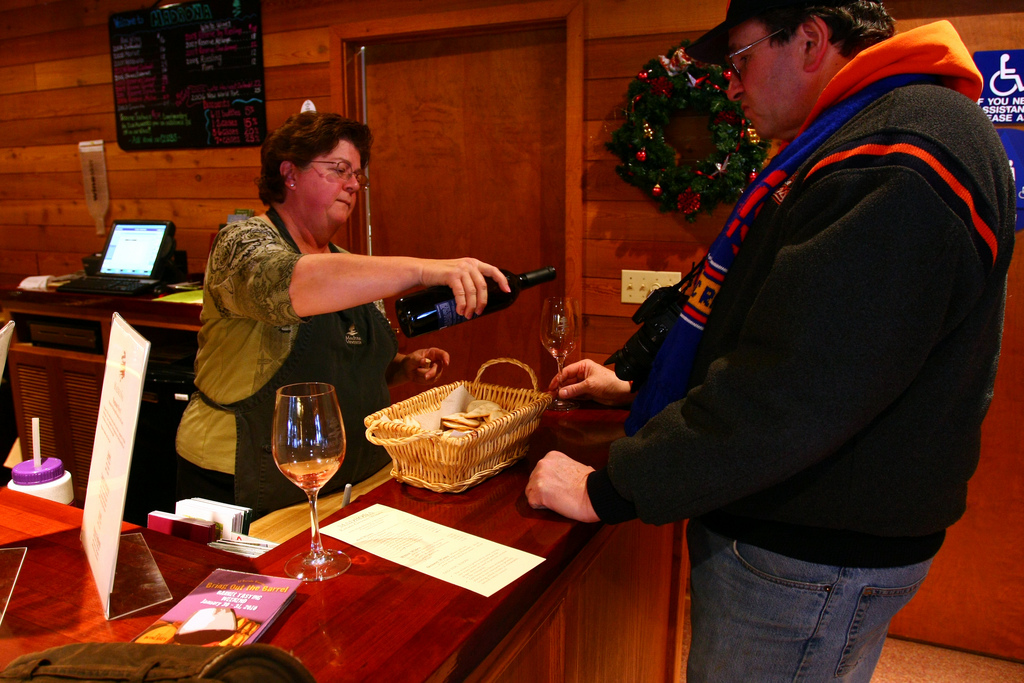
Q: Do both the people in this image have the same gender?
A: No, they are both male and female.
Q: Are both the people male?
A: No, they are both male and female.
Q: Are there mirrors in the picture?
A: No, there are no mirrors.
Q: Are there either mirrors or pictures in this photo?
A: No, there are no mirrors or pictures.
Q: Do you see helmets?
A: No, there are no helmets.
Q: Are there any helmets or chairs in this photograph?
A: No, there are no helmets or chairs.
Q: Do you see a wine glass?
A: Yes, there is a wine glass.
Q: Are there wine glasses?
A: Yes, there is a wine glass.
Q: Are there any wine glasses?
A: Yes, there is a wine glass.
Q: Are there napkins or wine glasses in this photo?
A: Yes, there is a wine glass.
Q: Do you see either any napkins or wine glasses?
A: Yes, there is a wine glass.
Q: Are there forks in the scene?
A: No, there are no forks.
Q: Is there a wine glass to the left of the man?
A: Yes, there is a wine glass to the left of the man.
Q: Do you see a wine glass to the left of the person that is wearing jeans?
A: Yes, there is a wine glass to the left of the man.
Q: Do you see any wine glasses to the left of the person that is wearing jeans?
A: Yes, there is a wine glass to the left of the man.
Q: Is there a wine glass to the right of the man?
A: No, the wine glass is to the left of the man.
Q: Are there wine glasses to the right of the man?
A: No, the wine glass is to the left of the man.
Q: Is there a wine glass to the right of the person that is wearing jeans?
A: No, the wine glass is to the left of the man.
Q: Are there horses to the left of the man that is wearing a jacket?
A: No, there is a wine glass to the left of the man.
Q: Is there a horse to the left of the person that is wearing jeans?
A: No, there is a wine glass to the left of the man.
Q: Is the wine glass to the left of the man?
A: Yes, the wine glass is to the left of the man.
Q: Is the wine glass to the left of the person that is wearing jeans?
A: Yes, the wine glass is to the left of the man.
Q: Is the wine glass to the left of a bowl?
A: No, the wine glass is to the left of the man.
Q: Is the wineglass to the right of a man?
A: No, the wineglass is to the left of a man.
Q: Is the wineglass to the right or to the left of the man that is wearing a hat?
A: The wineglass is to the left of the man.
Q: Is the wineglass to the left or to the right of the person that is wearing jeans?
A: The wineglass is to the left of the man.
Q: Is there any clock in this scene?
A: No, there are no clocks.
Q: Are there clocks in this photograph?
A: No, there are no clocks.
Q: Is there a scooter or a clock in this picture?
A: No, there are no clocks or scooters.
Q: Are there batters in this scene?
A: No, there are no batters.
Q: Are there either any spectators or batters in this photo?
A: No, there are no batters or spectators.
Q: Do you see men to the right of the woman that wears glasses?
A: Yes, there is a man to the right of the woman.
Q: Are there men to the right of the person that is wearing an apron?
A: Yes, there is a man to the right of the woman.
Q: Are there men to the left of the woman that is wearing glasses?
A: No, the man is to the right of the woman.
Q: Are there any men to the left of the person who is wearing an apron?
A: No, the man is to the right of the woman.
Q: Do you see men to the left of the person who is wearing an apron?
A: No, the man is to the right of the woman.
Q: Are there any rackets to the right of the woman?
A: No, there is a man to the right of the woman.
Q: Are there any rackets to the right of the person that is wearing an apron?
A: No, there is a man to the right of the woman.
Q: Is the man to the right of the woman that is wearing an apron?
A: Yes, the man is to the right of the woman.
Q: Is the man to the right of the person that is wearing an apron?
A: Yes, the man is to the right of the woman.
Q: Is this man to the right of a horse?
A: No, the man is to the right of the woman.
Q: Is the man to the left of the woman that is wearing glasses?
A: No, the man is to the right of the woman.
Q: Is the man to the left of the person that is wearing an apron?
A: No, the man is to the right of the woman.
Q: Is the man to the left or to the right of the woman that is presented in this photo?
A: The man is to the right of the woman.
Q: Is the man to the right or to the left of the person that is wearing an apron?
A: The man is to the right of the woman.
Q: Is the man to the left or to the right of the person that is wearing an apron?
A: The man is to the right of the woman.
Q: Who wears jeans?
A: The man wears jeans.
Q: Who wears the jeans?
A: The man wears jeans.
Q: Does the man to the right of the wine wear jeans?
A: Yes, the man wears jeans.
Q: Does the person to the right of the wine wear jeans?
A: Yes, the man wears jeans.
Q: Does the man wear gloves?
A: No, the man wears jeans.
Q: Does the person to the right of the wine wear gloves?
A: No, the man wears jeans.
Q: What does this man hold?
A: The man holds the glass.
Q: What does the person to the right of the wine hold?
A: The man holds the glass.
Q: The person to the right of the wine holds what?
A: The man holds the glass.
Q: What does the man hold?
A: The man holds the glass.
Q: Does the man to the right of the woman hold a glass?
A: Yes, the man holds a glass.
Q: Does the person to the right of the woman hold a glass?
A: Yes, the man holds a glass.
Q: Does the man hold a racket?
A: No, the man holds a glass.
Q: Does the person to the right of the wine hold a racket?
A: No, the man holds a glass.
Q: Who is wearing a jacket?
A: The man is wearing a jacket.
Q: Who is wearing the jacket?
A: The man is wearing a jacket.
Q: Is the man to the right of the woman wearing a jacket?
A: Yes, the man is wearing a jacket.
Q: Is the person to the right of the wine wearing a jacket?
A: Yes, the man is wearing a jacket.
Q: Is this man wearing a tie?
A: No, the man is wearing a jacket.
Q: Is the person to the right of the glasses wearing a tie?
A: No, the man is wearing a jacket.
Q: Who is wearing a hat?
A: The man is wearing a hat.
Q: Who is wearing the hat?
A: The man is wearing a hat.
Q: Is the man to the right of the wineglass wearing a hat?
A: Yes, the man is wearing a hat.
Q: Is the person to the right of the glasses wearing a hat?
A: Yes, the man is wearing a hat.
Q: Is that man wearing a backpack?
A: No, the man is wearing a hat.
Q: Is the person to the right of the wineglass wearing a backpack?
A: No, the man is wearing a hat.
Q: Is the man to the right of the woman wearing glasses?
A: Yes, the man is wearing glasses.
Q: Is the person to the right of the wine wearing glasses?
A: Yes, the man is wearing glasses.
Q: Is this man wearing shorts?
A: No, the man is wearing glasses.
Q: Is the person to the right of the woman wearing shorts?
A: No, the man is wearing glasses.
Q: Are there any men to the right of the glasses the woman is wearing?
A: Yes, there is a man to the right of the glasses.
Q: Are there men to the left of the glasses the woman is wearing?
A: No, the man is to the right of the glasses.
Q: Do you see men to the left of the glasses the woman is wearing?
A: No, the man is to the right of the glasses.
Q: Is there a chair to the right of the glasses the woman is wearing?
A: No, there is a man to the right of the glasses.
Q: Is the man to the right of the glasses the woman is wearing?
A: Yes, the man is to the right of the glasses.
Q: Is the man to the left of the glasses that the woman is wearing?
A: No, the man is to the right of the glasses.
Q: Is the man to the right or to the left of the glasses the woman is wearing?
A: The man is to the right of the glasses.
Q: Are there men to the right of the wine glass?
A: Yes, there is a man to the right of the wine glass.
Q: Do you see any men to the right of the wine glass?
A: Yes, there is a man to the right of the wine glass.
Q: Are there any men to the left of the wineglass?
A: No, the man is to the right of the wineglass.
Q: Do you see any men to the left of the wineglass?
A: No, the man is to the right of the wineglass.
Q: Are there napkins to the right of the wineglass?
A: No, there is a man to the right of the wineglass.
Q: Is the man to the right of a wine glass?
A: Yes, the man is to the right of a wine glass.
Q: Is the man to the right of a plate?
A: No, the man is to the right of a wine glass.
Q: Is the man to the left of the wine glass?
A: No, the man is to the right of the wine glass.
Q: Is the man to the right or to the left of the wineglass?
A: The man is to the right of the wineglass.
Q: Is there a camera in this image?
A: Yes, there is a camera.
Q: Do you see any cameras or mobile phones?
A: Yes, there is a camera.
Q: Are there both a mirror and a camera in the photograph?
A: No, there is a camera but no mirrors.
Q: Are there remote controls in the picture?
A: No, there are no remote controls.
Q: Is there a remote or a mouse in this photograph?
A: No, there are no remote controls or computer mice.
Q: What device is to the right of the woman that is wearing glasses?
A: The device is a camera.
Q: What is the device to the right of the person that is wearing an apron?
A: The device is a camera.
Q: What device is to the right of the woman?
A: The device is a camera.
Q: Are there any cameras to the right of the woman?
A: Yes, there is a camera to the right of the woman.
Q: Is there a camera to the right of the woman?
A: Yes, there is a camera to the right of the woman.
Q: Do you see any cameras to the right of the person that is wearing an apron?
A: Yes, there is a camera to the right of the woman.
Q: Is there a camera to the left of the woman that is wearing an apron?
A: No, the camera is to the right of the woman.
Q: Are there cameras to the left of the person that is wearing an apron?
A: No, the camera is to the right of the woman.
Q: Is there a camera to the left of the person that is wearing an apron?
A: No, the camera is to the right of the woman.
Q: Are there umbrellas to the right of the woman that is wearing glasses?
A: No, there is a camera to the right of the woman.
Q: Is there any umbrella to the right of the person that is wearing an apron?
A: No, there is a camera to the right of the woman.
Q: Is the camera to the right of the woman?
A: Yes, the camera is to the right of the woman.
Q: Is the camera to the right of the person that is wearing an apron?
A: Yes, the camera is to the right of the woman.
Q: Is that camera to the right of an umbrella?
A: No, the camera is to the right of the woman.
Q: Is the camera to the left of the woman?
A: No, the camera is to the right of the woman.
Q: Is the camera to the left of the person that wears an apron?
A: No, the camera is to the right of the woman.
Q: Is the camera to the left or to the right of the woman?
A: The camera is to the right of the woman.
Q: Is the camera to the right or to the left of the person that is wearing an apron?
A: The camera is to the right of the woman.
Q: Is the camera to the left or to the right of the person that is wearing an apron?
A: The camera is to the right of the woman.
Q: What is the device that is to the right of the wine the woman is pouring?
A: The device is a camera.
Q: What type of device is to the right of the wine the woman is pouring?
A: The device is a camera.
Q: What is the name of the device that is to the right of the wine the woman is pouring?
A: The device is a camera.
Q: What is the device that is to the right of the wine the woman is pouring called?
A: The device is a camera.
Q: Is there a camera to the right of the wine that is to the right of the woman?
A: Yes, there is a camera to the right of the wine.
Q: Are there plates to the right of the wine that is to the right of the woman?
A: No, there is a camera to the right of the wine.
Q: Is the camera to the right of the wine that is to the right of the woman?
A: Yes, the camera is to the right of the wine.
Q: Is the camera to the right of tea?
A: No, the camera is to the right of the wine.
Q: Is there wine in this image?
A: Yes, there is wine.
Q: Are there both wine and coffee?
A: No, there is wine but no coffee.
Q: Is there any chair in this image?
A: No, there are no chairs.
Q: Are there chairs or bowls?
A: No, there are no chairs or bowls.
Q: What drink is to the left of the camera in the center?
A: The drink is wine.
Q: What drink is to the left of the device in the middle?
A: The drink is wine.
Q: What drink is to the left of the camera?
A: The drink is wine.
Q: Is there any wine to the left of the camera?
A: Yes, there is wine to the left of the camera.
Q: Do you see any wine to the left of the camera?
A: Yes, there is wine to the left of the camera.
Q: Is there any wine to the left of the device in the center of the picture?
A: Yes, there is wine to the left of the camera.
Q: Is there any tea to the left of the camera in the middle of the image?
A: No, there is wine to the left of the camera.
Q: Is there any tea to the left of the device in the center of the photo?
A: No, there is wine to the left of the camera.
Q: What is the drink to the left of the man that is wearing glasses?
A: The drink is wine.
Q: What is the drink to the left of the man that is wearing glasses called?
A: The drink is wine.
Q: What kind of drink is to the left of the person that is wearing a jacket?
A: The drink is wine.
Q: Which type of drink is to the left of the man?
A: The drink is wine.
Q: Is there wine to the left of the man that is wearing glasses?
A: Yes, there is wine to the left of the man.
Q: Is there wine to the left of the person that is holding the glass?
A: Yes, there is wine to the left of the man.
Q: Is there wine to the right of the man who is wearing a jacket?
A: No, the wine is to the left of the man.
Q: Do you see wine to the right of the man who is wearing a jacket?
A: No, the wine is to the left of the man.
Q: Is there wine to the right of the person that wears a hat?
A: No, the wine is to the left of the man.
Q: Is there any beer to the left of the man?
A: No, there is wine to the left of the man.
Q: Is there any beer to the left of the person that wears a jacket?
A: No, there is wine to the left of the man.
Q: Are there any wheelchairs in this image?
A: No, there are no wheelchairs.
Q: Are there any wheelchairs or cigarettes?
A: No, there are no wheelchairs or cigarettes.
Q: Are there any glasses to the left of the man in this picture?
A: Yes, there are glasses to the left of the man.